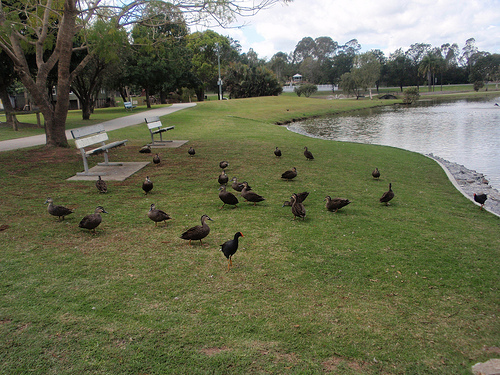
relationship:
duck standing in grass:
[218, 226, 243, 265] [6, 90, 499, 374]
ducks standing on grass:
[41, 136, 400, 269] [6, 90, 499, 374]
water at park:
[293, 87, 493, 218] [1, 1, 497, 375]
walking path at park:
[3, 88, 195, 153] [1, 1, 497, 375]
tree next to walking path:
[1, 2, 264, 147] [3, 88, 195, 153]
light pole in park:
[214, 52, 230, 99] [1, 1, 497, 375]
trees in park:
[1, 2, 500, 111] [1, 1, 497, 375]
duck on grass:
[283, 163, 297, 180] [6, 90, 499, 374]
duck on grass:
[324, 193, 352, 216] [6, 90, 499, 374]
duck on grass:
[187, 146, 199, 154] [6, 90, 499, 374]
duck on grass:
[140, 175, 159, 195] [6, 90, 499, 374]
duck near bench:
[187, 146, 199, 154] [144, 116, 176, 148]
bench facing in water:
[144, 116, 176, 148] [293, 87, 493, 218]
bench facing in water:
[74, 123, 129, 174] [293, 87, 493, 218]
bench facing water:
[144, 116, 176, 148] [293, 87, 493, 218]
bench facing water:
[74, 123, 129, 174] [293, 87, 493, 218]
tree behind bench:
[1, 2, 264, 147] [144, 116, 176, 148]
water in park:
[293, 87, 493, 218] [1, 1, 497, 375]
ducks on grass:
[41, 136, 400, 269] [6, 90, 499, 374]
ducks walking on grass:
[41, 136, 400, 269] [6, 90, 499, 374]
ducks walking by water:
[41, 136, 400, 269] [293, 87, 493, 218]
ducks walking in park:
[41, 136, 400, 269] [1, 1, 497, 375]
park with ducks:
[1, 1, 497, 375] [41, 136, 400, 269]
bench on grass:
[144, 116, 176, 148] [6, 90, 499, 374]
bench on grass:
[74, 123, 129, 174] [6, 90, 499, 374]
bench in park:
[144, 116, 176, 148] [1, 1, 497, 375]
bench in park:
[74, 123, 129, 174] [1, 1, 497, 375]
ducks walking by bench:
[41, 136, 400, 269] [144, 116, 176, 148]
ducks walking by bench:
[41, 136, 400, 269] [74, 123, 129, 174]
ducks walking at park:
[41, 136, 400, 269] [1, 1, 497, 375]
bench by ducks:
[144, 116, 176, 148] [41, 136, 400, 269]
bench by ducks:
[74, 123, 129, 174] [41, 136, 400, 269]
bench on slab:
[144, 116, 176, 148] [152, 134, 191, 150]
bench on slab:
[74, 123, 129, 174] [75, 160, 147, 185]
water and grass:
[293, 87, 493, 218] [6, 90, 499, 374]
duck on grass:
[218, 226, 243, 265] [6, 90, 499, 374]